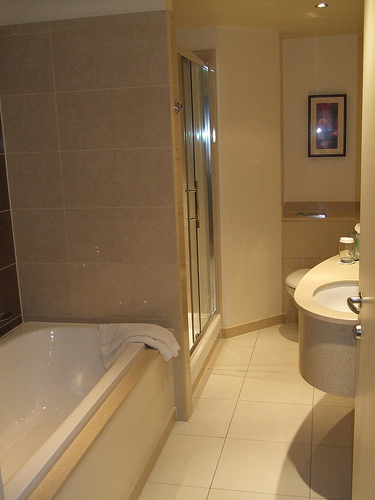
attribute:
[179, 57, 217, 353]
door — glass, silver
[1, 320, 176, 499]
bathtub — white, deep, long, procelain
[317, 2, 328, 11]
lighting — on, overhead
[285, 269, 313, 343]
toilet — white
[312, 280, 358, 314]
sink — round, deep, white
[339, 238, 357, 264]
jar — glass, small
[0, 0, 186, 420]
wall — tan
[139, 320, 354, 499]
tile — large, ceramic, white, tan, square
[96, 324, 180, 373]
towel — white, folded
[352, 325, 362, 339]
lock — silver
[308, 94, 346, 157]
picture — rectangular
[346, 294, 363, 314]
handle — silver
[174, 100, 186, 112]
hook — silver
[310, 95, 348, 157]
frame — dark